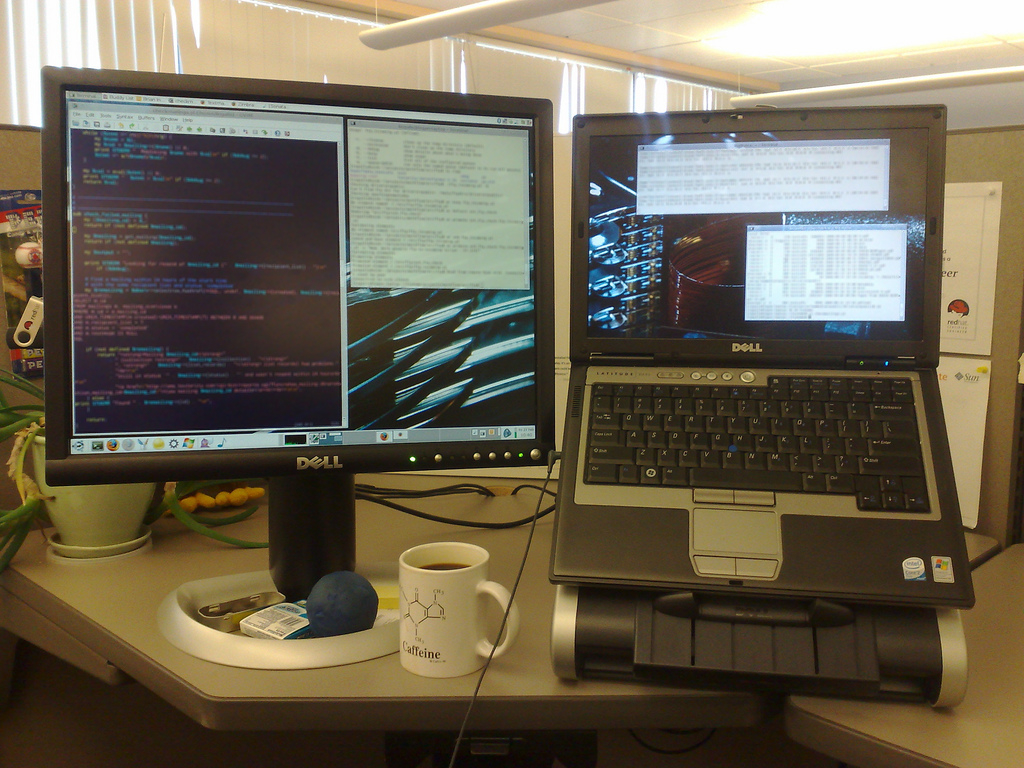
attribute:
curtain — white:
[4, 3, 635, 138]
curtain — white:
[637, 74, 754, 114]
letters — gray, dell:
[728, 335, 761, 357]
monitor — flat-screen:
[28, 52, 564, 487]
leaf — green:
[169, 492, 269, 536]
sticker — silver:
[922, 540, 959, 592]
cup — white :
[363, 480, 498, 710]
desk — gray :
[39, 476, 807, 764]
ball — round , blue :
[294, 521, 401, 642]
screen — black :
[21, 44, 583, 531]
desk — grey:
[154, 443, 563, 672]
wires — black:
[426, 480, 543, 580]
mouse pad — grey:
[673, 487, 790, 568]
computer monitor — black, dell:
[46, 59, 578, 515]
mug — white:
[394, 525, 533, 681]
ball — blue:
[314, 562, 384, 632]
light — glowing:
[684, 16, 993, 53]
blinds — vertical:
[163, 22, 334, 68]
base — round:
[55, 523, 153, 556]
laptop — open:
[569, 107, 967, 697]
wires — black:
[400, 472, 537, 531]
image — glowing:
[651, 163, 874, 310]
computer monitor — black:
[36, 72, 548, 476]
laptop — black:
[565, 121, 978, 610]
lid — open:
[560, 89, 956, 357]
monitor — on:
[44, 85, 570, 459]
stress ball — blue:
[275, 577, 394, 627]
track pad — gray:
[683, 497, 789, 569]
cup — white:
[391, 534, 521, 682]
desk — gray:
[8, 476, 992, 753]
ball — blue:
[307, 565, 385, 633]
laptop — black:
[546, 100, 979, 718]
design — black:
[401, 577, 462, 660]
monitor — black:
[30, 59, 564, 671]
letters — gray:
[287, 446, 340, 472]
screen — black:
[36, 61, 562, 474]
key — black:
[715, 448, 748, 474]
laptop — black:
[538, 94, 982, 620]